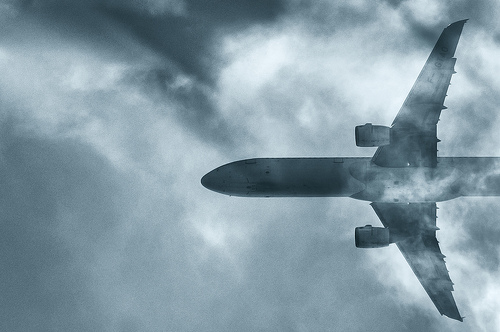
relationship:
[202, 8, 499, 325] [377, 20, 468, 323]
airplane has wings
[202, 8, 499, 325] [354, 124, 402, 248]
plane has engine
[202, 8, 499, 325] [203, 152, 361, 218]
plane has nose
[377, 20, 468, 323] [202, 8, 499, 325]
wing of a plane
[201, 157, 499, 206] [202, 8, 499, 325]
body of a plane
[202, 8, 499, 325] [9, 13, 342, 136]
plane between clouds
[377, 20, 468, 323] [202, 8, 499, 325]
wings of an plane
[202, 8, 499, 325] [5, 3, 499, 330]
plane in sky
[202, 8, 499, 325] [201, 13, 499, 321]
plane has nose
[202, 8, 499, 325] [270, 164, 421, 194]
plane has underbelly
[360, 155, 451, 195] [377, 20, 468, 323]
jet engine under wings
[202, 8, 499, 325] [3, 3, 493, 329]
plane in clouds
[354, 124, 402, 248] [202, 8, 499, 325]
engine on side of plane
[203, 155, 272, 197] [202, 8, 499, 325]
cockpit on plane